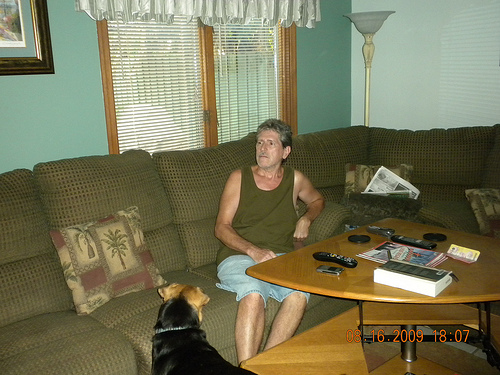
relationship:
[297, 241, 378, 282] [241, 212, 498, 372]
controller on table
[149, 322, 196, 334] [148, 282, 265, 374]
collar on dog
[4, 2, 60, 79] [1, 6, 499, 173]
picture on wall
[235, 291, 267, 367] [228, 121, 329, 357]
leg of man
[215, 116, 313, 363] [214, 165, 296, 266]
man wearing tank top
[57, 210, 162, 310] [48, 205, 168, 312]
palm trees on pillow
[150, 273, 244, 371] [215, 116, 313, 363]
dog looking at man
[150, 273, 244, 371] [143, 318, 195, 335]
dog wearing collar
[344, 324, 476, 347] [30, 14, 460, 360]
numbers on picture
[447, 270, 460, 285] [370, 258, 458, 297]
bookmark in book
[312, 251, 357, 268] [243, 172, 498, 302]
controller sitting on table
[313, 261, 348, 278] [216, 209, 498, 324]
cell phone sitting on table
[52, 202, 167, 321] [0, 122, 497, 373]
pillow sitting on couch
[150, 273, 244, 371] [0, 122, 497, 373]
dog standing in front couch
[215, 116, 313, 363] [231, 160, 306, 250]
man standing in in tank top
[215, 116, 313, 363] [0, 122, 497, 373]
man sitting on couch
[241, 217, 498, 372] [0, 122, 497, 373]
coffee table sitting in front couch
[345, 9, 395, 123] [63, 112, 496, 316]
floor lamp sitting behind couch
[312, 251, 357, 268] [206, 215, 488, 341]
controller sitting on table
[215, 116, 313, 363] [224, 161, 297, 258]
man wearing tank top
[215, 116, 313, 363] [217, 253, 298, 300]
man wearing shorts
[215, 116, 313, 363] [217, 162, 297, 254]
man wearing tank top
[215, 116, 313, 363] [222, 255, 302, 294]
man wearing shorts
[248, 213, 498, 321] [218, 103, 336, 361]
table in front of man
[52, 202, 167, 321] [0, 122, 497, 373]
pillow on couch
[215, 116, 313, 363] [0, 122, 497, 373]
man next to couch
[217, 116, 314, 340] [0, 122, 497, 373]
man sitting on couch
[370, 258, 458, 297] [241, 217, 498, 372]
book lying on coffee table